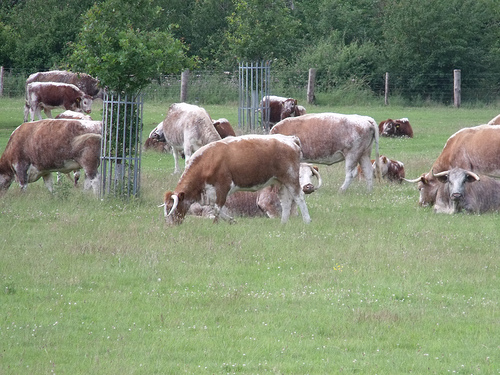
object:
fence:
[99, 89, 144, 202]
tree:
[67, 0, 191, 204]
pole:
[452, 69, 464, 108]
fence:
[145, 65, 500, 110]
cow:
[398, 122, 498, 207]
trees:
[1, 1, 500, 76]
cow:
[157, 133, 313, 226]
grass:
[0, 97, 499, 374]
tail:
[366, 117, 383, 184]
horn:
[169, 194, 178, 217]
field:
[1, 97, 498, 375]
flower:
[31, 326, 36, 333]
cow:
[378, 117, 414, 138]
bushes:
[276, 21, 414, 106]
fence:
[235, 60, 281, 133]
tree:
[226, 0, 305, 135]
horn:
[465, 171, 482, 183]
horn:
[432, 169, 451, 178]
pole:
[180, 69, 189, 101]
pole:
[306, 67, 317, 103]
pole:
[385, 72, 393, 106]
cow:
[199, 163, 321, 218]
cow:
[370, 155, 406, 184]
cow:
[432, 167, 500, 214]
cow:
[265, 112, 385, 191]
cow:
[0, 118, 104, 194]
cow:
[25, 82, 93, 120]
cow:
[25, 69, 104, 100]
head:
[436, 167, 479, 199]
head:
[158, 192, 192, 226]